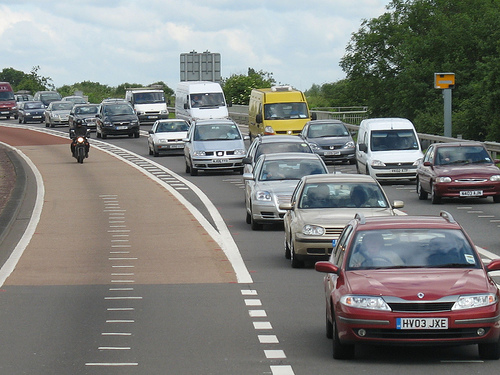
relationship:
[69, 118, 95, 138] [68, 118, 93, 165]
man on motorcycle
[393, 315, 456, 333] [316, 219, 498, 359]
license plate on front of car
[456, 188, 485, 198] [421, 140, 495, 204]
license plate on front of car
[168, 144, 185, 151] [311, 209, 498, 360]
license plate on front of car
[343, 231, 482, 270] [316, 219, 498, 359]
windshield on front of car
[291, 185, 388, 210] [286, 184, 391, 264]
windshield on front of car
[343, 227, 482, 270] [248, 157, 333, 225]
windshield on front of car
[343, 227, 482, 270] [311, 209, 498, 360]
windshield on front of car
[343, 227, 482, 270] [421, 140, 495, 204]
windshield on front of car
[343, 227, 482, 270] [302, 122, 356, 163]
windshield on front of car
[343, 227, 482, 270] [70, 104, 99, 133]
windshield on front of car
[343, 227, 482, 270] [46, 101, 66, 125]
windshield on front of car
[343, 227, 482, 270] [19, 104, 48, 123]
windshield on front of car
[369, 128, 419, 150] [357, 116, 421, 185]
windshield on front of van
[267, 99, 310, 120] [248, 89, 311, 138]
windshield on front of van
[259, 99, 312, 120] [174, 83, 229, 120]
windshield on front of van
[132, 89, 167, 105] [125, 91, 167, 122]
windshield on front of van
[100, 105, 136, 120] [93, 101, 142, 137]
windshield on front of van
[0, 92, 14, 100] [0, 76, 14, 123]
windshield on front of van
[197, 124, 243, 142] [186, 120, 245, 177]
windshield on front of van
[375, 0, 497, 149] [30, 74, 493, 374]
trees on side of road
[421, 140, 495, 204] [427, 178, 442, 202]
car has tire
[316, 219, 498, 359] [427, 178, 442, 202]
car has tire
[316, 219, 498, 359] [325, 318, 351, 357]
car has tire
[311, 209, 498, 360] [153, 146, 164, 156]
car has tire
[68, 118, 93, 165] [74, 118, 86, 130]
man wearing helmet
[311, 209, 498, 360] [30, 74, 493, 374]
car on road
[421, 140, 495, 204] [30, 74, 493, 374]
car on road